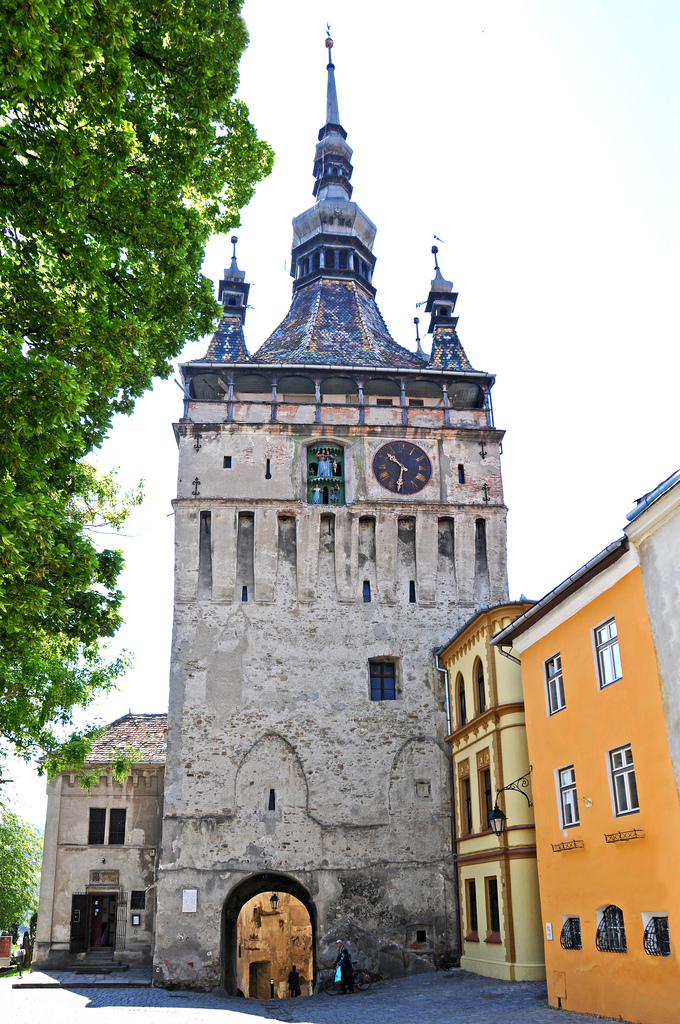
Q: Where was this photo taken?
A: In front of the church.